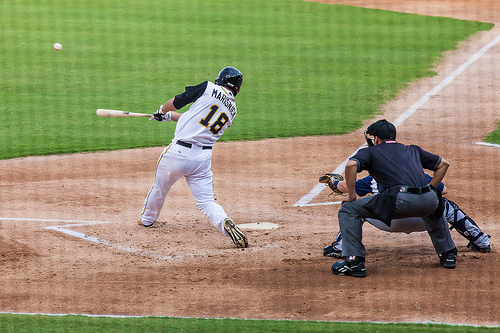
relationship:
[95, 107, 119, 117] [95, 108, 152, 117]
part of bat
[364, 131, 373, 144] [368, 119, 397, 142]
part of cap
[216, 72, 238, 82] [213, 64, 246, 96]
part of helmet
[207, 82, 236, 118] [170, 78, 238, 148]
part of top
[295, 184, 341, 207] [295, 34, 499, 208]
part of line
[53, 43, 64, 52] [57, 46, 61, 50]
baseball has part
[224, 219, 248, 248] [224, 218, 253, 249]
sole of shoe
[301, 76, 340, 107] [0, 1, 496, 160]
part of ground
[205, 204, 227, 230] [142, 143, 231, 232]
part of trouser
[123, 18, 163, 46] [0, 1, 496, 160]
part of ground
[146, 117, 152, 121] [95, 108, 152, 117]
part of bat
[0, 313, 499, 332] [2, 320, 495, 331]
edge of grass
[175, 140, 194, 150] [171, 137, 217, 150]
part of belt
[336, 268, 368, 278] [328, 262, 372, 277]
part of shoe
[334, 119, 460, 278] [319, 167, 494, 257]
umpire behind catcher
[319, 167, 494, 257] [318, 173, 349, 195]
catcher has mitt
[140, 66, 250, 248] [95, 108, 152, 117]
player swinging bat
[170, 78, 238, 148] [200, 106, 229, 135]
shirt has number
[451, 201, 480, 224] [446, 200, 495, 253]
shin guard on leg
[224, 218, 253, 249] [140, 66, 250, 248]
shoe of man